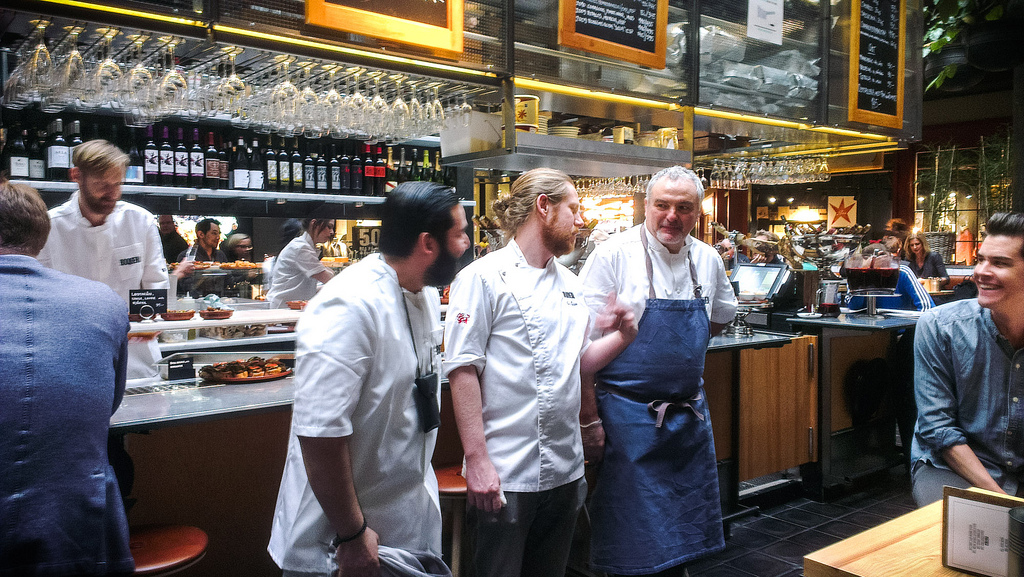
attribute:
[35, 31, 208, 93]
glasses — overhead, hanging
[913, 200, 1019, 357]
man — wearing, behind, laughing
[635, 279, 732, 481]
apron — blue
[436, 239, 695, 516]
coat — white, chef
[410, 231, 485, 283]
beard — dark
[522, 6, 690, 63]
frame — wooden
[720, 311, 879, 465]
door — swinging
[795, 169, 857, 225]
star — red, hanging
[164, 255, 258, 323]
vessel — here, made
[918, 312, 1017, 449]
shirt — blue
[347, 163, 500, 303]
hair — dark, blond, black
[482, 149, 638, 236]
hair — long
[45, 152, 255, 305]
chef — working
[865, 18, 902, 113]
chalkboards — written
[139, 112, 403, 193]
bottles — rowed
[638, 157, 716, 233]
hair — grey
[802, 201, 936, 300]
woman — sitting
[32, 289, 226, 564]
coat — blue